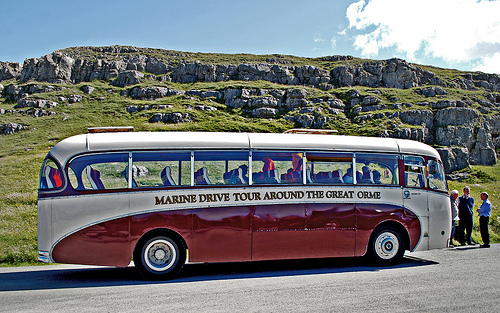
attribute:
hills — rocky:
[6, 44, 499, 238]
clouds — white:
[347, 2, 498, 77]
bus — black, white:
[37, 117, 459, 271]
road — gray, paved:
[1, 237, 499, 307]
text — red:
[145, 185, 379, 202]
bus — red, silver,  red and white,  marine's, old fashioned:
[33, 131, 456, 285]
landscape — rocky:
[90, 38, 478, 144]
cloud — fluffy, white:
[346, 14, 496, 79]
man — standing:
[443, 186, 488, 242]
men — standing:
[442, 194, 494, 251]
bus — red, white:
[48, 140, 439, 262]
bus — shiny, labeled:
[45, 137, 477, 278]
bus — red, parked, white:
[50, 131, 444, 291]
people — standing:
[435, 183, 499, 245]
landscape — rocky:
[96, 55, 379, 122]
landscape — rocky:
[54, 46, 456, 125]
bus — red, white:
[59, 131, 453, 263]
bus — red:
[45, 136, 482, 250]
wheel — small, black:
[137, 230, 215, 297]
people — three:
[449, 185, 493, 248]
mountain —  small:
[0, 45, 498, 123]